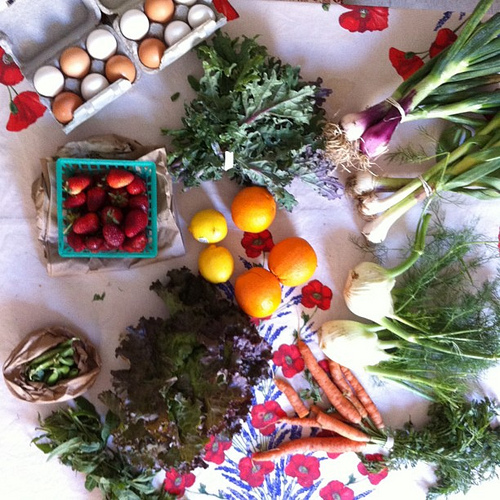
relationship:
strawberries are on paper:
[62, 169, 152, 254] [34, 144, 191, 271]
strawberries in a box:
[62, 169, 152, 254] [48, 158, 164, 268]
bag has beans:
[12, 335, 102, 401] [26, 355, 87, 384]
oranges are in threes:
[230, 189, 315, 321] [234, 188, 314, 315]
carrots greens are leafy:
[241, 335, 494, 488] [391, 397, 500, 499]